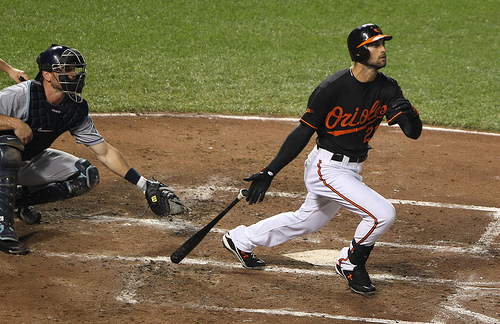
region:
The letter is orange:
[322, 100, 343, 132]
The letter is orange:
[337, 108, 350, 130]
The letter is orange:
[348, 101, 361, 135]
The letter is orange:
[358, 103, 370, 128]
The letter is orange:
[366, 91, 381, 126]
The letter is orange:
[373, 103, 383, 125]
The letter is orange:
[378, 95, 389, 120]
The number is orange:
[361, 125, 373, 145]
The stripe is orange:
[313, 154, 381, 251]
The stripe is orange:
[297, 110, 318, 135]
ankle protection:
[350, 235, 370, 262]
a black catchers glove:
[143, 180, 185, 219]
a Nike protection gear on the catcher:
[22, 85, 87, 156]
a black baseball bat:
[172, 184, 252, 264]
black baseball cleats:
[333, 260, 375, 293]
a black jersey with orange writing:
[300, 71, 402, 147]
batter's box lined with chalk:
[148, 178, 492, 248]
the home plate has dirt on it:
[282, 245, 340, 270]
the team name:
[327, 103, 387, 138]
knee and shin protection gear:
[0, 139, 27, 243]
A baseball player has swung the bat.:
[169, 24, 423, 296]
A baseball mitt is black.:
[140, 175, 180, 220]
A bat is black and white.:
[165, 190, 245, 260]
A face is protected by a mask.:
[52, 45, 97, 102]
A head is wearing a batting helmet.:
[346, 20, 392, 60]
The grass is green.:
[0, 0, 499, 133]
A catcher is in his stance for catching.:
[0, 40, 185, 256]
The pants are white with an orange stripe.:
[227, 155, 380, 261]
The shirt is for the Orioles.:
[298, 70, 404, 151]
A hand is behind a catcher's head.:
[0, 44, 188, 254]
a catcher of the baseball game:
[11, 51, 164, 241]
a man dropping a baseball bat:
[163, 19, 425, 299]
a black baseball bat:
[168, 185, 254, 255]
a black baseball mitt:
[142, 167, 184, 213]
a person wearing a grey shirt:
[4, 46, 147, 202]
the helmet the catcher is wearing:
[38, 45, 90, 103]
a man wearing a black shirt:
[239, 23, 411, 289]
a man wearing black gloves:
[243, 22, 419, 286]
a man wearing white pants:
[240, 19, 421, 291]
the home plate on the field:
[289, 248, 364, 261]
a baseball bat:
[168, 241, 209, 261]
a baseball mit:
[142, 182, 189, 222]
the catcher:
[1, 45, 113, 217]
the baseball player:
[335, 257, 377, 298]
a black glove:
[245, 168, 272, 203]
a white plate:
[293, 244, 332, 265]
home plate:
[281, 247, 343, 267]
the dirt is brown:
[435, 153, 475, 190]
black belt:
[332, 152, 342, 163]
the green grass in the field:
[205, 14, 299, 64]